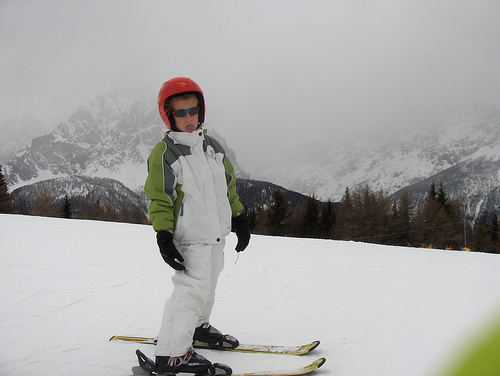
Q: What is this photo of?
A: A snow day.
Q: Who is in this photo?
A: A girl.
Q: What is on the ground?
A: Snow.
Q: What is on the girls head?
A: A helmet.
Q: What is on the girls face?
A: Glasses.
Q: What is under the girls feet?
A: Skis.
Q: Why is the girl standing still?
A: Posing for a picture.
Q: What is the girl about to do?
A: Ski.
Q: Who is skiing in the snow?
A: The boy.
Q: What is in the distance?
A: Mountain range.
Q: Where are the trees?
A: In the valley.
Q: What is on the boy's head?
A: Helmet.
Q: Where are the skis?
A: On the boy's feet.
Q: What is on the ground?
A: Snow.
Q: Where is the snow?
A: On the ground.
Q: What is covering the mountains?
A: Snow.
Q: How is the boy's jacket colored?
A: Green, white, and gray.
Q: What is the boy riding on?
A: Skis.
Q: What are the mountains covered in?
A: Snow.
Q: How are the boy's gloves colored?
A: Black.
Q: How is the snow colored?
A: White.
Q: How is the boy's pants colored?
A: White.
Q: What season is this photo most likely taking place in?
A: Winter.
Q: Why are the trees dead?
A: It is out of season.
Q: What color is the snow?
A: White.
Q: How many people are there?
A: One.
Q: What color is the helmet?
A: Red.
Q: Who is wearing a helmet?
A: The man.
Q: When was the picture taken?
A: Daytime.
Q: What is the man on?
A: Skis.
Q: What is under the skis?
A: Snow.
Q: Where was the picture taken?
A: Mountain.